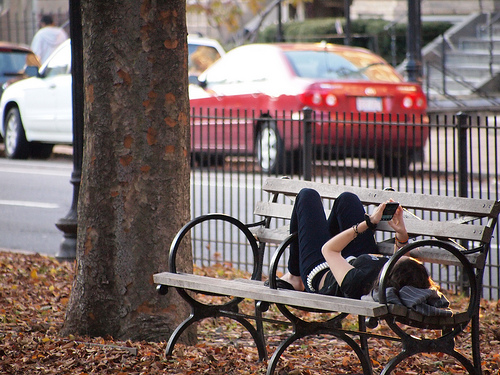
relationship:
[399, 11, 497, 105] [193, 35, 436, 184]
stairs behind car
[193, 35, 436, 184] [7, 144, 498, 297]
car on street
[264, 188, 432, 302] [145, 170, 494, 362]
girl laying on bench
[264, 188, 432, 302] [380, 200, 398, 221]
girl holding phone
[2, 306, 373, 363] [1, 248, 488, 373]
leaves are on ground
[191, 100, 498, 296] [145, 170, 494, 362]
fence behind bench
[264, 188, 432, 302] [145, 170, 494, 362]
girl on bench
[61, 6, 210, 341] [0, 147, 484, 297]
tree by road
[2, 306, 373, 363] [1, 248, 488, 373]
leaves on ground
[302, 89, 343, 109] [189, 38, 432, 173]
lights are on car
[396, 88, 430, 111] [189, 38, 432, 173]
lights are on car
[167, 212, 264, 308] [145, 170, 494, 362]
circle on bench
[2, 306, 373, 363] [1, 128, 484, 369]
leaves on ground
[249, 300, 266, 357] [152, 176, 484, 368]
pole under bench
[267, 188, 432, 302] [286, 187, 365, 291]
girl wearing pants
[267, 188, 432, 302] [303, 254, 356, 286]
girl wearing belt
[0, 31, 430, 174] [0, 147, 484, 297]
cars on road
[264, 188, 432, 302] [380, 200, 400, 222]
girl holding cell phone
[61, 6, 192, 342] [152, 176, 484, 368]
tree next to bench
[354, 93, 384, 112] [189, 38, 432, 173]
plate on car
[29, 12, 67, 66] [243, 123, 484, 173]
man on sidewalk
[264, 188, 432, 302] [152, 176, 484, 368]
girl on bench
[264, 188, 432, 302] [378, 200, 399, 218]
girl holding cellphone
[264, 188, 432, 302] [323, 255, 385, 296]
girl wearing shirt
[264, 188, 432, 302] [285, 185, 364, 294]
girl wearing jeans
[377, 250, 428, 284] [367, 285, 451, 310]
head on jacket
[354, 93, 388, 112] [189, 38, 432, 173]
plate on car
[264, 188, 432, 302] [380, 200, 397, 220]
girl looking at cellphone